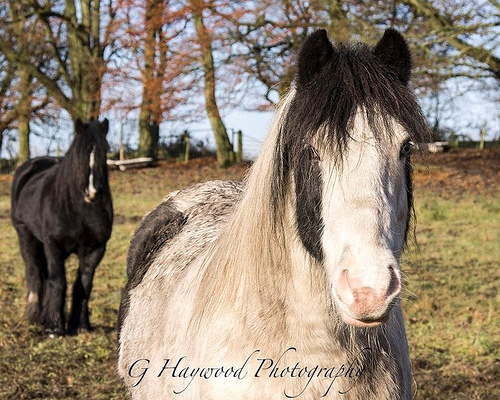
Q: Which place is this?
A: It is a field.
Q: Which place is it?
A: It is a field.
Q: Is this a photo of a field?
A: Yes, it is showing a field.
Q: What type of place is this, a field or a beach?
A: It is a field.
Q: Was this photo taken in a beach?
A: No, the picture was taken in a field.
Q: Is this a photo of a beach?
A: No, the picture is showing a field.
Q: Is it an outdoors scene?
A: Yes, it is outdoors.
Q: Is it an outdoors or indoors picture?
A: It is outdoors.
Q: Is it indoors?
A: No, it is outdoors.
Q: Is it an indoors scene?
A: No, it is outdoors.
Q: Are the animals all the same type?
A: Yes, all the animals are horses.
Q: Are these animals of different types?
A: No, all the animals are horses.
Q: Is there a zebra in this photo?
A: No, there are no zebras.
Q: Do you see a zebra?
A: No, there are no zebras.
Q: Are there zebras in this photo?
A: No, there are no zebras.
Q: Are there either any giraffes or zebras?
A: No, there are no zebras or giraffes.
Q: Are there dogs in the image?
A: No, there are no dogs.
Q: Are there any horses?
A: Yes, there are horses.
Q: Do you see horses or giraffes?
A: Yes, there are horses.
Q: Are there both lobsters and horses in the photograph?
A: No, there are horses but no lobsters.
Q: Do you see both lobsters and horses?
A: No, there are horses but no lobsters.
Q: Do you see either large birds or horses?
A: Yes, there are large horses.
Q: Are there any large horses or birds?
A: Yes, there are large horses.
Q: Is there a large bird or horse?
A: Yes, there are large horses.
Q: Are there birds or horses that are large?
A: Yes, the horses are large.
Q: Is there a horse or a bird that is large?
A: Yes, the horses are large.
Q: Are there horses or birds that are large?
A: Yes, the horses are large.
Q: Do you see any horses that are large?
A: Yes, there are large horses.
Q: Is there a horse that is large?
A: Yes, there are horses that are large.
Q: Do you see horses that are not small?
A: Yes, there are large horses.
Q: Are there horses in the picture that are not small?
A: Yes, there are large horses.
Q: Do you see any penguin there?
A: No, there are no penguins.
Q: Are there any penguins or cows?
A: No, there are no penguins or cows.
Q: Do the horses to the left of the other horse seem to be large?
A: Yes, the horses are large.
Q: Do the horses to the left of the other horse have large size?
A: Yes, the horses are large.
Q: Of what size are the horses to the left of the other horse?
A: The horses are large.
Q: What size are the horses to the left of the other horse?
A: The horses are large.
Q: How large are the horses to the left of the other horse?
A: The horses are large.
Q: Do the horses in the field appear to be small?
A: No, the horses are large.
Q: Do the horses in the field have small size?
A: No, the horses are large.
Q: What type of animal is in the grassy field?
A: The animals are horses.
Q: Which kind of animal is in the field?
A: The animals are horses.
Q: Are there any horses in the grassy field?
A: Yes, there are horses in the field.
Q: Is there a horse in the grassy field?
A: Yes, there are horses in the field.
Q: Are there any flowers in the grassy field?
A: No, there are horses in the field.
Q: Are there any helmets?
A: No, there are no helmets.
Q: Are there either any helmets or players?
A: No, there are no helmets or players.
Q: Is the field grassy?
A: Yes, the field is grassy.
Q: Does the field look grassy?
A: Yes, the field is grassy.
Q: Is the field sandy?
A: No, the field is grassy.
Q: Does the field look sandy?
A: No, the field is grassy.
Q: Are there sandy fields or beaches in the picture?
A: No, there is a field but it is grassy.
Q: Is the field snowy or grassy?
A: The field is grassy.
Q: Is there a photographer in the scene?
A: Yes, there is a photographer.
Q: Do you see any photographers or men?
A: Yes, there is a photographer.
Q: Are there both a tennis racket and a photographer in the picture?
A: No, there is a photographer but no rackets.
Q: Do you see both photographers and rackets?
A: No, there is a photographer but no rackets.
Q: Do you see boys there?
A: No, there are no boys.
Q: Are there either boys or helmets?
A: No, there are no boys or helmets.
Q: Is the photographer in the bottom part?
A: Yes, the photographer is in the bottom of the image.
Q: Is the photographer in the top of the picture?
A: No, the photographer is in the bottom of the image.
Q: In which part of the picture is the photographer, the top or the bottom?
A: The photographer is in the bottom of the image.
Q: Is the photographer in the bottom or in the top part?
A: The photographer is in the bottom of the image.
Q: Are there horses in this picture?
A: Yes, there is a horse.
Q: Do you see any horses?
A: Yes, there is a horse.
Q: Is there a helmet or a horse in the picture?
A: Yes, there is a horse.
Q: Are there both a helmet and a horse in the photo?
A: No, there is a horse but no helmets.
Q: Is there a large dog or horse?
A: Yes, there is a large horse.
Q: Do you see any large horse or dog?
A: Yes, there is a large horse.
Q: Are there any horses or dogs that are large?
A: Yes, the horse is large.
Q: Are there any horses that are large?
A: Yes, there is a large horse.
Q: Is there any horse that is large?
A: Yes, there is a horse that is large.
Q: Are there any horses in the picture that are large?
A: Yes, there is a horse that is large.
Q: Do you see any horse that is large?
A: Yes, there is a horse that is large.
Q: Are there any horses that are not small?
A: Yes, there is a large horse.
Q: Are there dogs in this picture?
A: No, there are no dogs.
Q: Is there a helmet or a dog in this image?
A: No, there are no dogs or helmets.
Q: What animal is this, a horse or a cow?
A: This is a horse.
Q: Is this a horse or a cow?
A: This is a horse.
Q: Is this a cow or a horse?
A: This is a horse.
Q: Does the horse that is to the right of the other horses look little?
A: No, the horse is large.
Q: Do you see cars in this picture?
A: No, there are no cars.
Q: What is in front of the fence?
A: The trees are in front of the fence.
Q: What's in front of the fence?
A: The trees are in front of the fence.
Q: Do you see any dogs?
A: No, there are no dogs.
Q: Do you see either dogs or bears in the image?
A: No, there are no dogs or bears.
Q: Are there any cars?
A: No, there are no cars.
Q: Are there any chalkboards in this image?
A: No, there are no chalkboards.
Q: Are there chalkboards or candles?
A: No, there are no chalkboards or candles.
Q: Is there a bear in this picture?
A: No, there are no bears.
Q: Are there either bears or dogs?
A: No, there are no bears or dogs.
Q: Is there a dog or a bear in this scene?
A: No, there are no bears or dogs.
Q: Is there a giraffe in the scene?
A: No, there are no giraffes.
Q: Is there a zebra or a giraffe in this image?
A: No, there are no giraffes or zebras.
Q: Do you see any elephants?
A: No, there are no elephants.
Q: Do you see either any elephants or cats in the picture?
A: No, there are no elephants or cats.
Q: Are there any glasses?
A: No, there are no glasses.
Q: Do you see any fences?
A: Yes, there is a fence.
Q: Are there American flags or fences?
A: Yes, there is a fence.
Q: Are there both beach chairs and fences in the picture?
A: No, there is a fence but no beach chairs.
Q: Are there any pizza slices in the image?
A: No, there are no pizza slices.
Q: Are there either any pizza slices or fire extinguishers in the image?
A: No, there are no pizza slices or fire extinguishers.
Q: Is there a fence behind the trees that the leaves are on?
A: Yes, there is a fence behind the trees.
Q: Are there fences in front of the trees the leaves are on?
A: No, the fence is behind the trees.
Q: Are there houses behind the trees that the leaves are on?
A: No, there is a fence behind the trees.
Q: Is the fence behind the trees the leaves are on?
A: Yes, the fence is behind the trees.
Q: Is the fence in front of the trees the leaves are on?
A: No, the fence is behind the trees.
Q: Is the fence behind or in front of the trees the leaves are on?
A: The fence is behind the trees.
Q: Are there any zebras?
A: No, there are no zebras.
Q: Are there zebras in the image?
A: No, there are no zebras.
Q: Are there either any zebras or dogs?
A: No, there are no zebras or dogs.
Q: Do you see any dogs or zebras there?
A: No, there are no zebras or dogs.